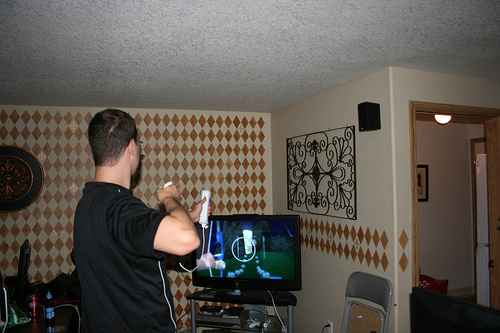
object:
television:
[187, 213, 303, 291]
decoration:
[284, 125, 358, 220]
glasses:
[136, 134, 148, 149]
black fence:
[0, 147, 43, 214]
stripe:
[157, 259, 182, 331]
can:
[24, 298, 44, 329]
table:
[0, 281, 69, 333]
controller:
[198, 189, 211, 224]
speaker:
[353, 100, 381, 132]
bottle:
[40, 289, 57, 331]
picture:
[412, 162, 430, 203]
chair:
[338, 270, 393, 331]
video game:
[192, 220, 294, 279]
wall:
[415, 120, 475, 303]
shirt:
[72, 182, 170, 331]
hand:
[191, 195, 211, 222]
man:
[69, 108, 214, 330]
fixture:
[435, 114, 453, 125]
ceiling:
[0, 0, 500, 110]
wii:
[162, 181, 173, 188]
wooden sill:
[487, 115, 500, 311]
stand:
[184, 290, 296, 332]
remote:
[156, 172, 186, 206]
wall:
[270, 61, 396, 333]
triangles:
[198, 129, 207, 142]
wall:
[0, 105, 272, 333]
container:
[409, 287, 451, 325]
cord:
[317, 321, 337, 331]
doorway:
[388, 59, 498, 329]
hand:
[154, 182, 182, 204]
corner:
[267, 107, 278, 213]